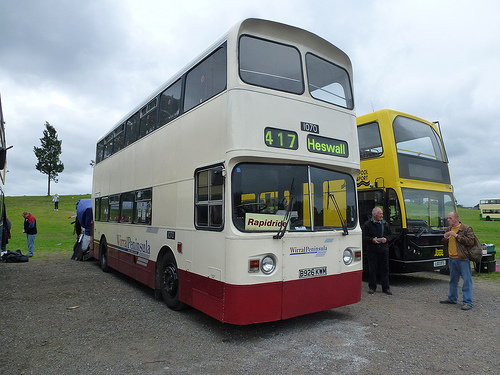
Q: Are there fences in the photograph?
A: No, there are no fences.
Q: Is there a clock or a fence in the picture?
A: No, there are no fences or clocks.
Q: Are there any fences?
A: No, there are no fences.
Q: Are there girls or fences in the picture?
A: No, there are no fences or girls.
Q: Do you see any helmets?
A: No, there are no helmets.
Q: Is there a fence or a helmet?
A: No, there are no helmets or fences.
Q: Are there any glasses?
A: No, there are no glasses.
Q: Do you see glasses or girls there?
A: No, there are no glasses or girls.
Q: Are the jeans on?
A: Yes, the jeans are on.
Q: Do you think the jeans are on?
A: Yes, the jeans are on.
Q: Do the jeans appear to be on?
A: Yes, the jeans are on.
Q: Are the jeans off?
A: No, the jeans are on.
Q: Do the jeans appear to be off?
A: No, the jeans are on.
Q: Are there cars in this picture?
A: No, there are no cars.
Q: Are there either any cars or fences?
A: No, there are no cars or fences.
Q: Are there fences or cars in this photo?
A: No, there are no cars or fences.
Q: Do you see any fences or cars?
A: No, there are no cars or fences.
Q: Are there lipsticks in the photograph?
A: No, there are no lipsticks.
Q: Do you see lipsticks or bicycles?
A: No, there are no lipsticks or bicycles.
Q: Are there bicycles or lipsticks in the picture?
A: No, there are no lipsticks or bicycles.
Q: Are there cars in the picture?
A: No, there are no cars.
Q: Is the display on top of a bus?
A: Yes, the display is on top of a bus.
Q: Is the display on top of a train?
A: No, the display is on top of a bus.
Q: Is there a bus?
A: Yes, there is a bus.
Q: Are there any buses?
A: Yes, there is a bus.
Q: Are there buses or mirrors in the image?
A: Yes, there is a bus.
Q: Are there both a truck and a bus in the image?
A: No, there is a bus but no trucks.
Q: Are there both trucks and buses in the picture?
A: No, there is a bus but no trucks.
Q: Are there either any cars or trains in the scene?
A: No, there are no cars or trains.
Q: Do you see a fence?
A: No, there are no fences.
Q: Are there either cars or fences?
A: No, there are no fences or cars.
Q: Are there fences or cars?
A: No, there are no fences or cars.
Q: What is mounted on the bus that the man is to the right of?
A: The sign is mounted on the bus.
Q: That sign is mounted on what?
A: The sign is mounted on the bus.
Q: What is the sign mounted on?
A: The sign is mounted on the bus.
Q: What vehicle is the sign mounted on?
A: The sign is mounted on the bus.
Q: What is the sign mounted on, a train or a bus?
A: The sign is mounted on a bus.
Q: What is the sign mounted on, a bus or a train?
A: The sign is mounted on a bus.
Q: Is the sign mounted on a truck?
A: No, the sign is mounted on the bus.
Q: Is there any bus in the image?
A: Yes, there is a bus.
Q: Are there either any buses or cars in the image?
A: Yes, there is a bus.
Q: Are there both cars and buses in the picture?
A: No, there is a bus but no cars.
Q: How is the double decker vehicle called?
A: The vehicle is a bus.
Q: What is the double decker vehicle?
A: The vehicle is a bus.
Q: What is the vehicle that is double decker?
A: The vehicle is a bus.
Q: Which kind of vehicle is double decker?
A: The vehicle is a bus.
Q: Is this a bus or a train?
A: This is a bus.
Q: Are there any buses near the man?
A: Yes, there is a bus near the man.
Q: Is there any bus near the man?
A: Yes, there is a bus near the man.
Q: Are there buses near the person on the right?
A: Yes, there is a bus near the man.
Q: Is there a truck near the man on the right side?
A: No, there is a bus near the man.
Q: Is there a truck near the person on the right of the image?
A: No, there is a bus near the man.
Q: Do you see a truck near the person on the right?
A: No, there is a bus near the man.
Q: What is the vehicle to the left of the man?
A: The vehicle is a bus.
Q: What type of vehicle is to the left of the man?
A: The vehicle is a bus.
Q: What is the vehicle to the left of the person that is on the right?
A: The vehicle is a bus.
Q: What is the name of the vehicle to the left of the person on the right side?
A: The vehicle is a bus.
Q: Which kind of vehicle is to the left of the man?
A: The vehicle is a bus.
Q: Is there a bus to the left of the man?
A: Yes, there is a bus to the left of the man.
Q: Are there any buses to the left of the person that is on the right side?
A: Yes, there is a bus to the left of the man.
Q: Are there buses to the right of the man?
A: No, the bus is to the left of the man.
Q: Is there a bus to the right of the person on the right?
A: No, the bus is to the left of the man.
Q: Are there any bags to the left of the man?
A: No, there is a bus to the left of the man.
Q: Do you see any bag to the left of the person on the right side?
A: No, there is a bus to the left of the man.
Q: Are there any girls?
A: No, there are no girls.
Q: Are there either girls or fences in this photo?
A: No, there are no girls or fences.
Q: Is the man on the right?
A: Yes, the man is on the right of the image.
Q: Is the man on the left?
A: No, the man is on the right of the image.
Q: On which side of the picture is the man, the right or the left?
A: The man is on the right of the image.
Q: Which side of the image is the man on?
A: The man is on the right of the image.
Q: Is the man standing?
A: Yes, the man is standing.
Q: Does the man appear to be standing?
A: Yes, the man is standing.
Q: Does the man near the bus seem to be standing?
A: Yes, the man is standing.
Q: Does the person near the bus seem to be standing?
A: Yes, the man is standing.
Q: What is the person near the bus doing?
A: The man is standing.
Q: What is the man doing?
A: The man is standing.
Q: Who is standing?
A: The man is standing.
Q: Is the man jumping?
A: No, the man is standing.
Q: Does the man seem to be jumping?
A: No, the man is standing.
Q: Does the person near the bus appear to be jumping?
A: No, the man is standing.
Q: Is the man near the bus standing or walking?
A: The man is standing.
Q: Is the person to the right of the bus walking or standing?
A: The man is standing.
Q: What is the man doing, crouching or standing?
A: The man is standing.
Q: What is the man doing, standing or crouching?
A: The man is standing.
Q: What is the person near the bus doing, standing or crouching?
A: The man is standing.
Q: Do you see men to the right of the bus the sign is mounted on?
A: Yes, there is a man to the right of the bus.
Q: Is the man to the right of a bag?
A: No, the man is to the right of the bus.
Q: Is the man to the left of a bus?
A: No, the man is to the right of a bus.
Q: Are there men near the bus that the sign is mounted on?
A: Yes, there is a man near the bus.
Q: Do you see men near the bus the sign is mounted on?
A: Yes, there is a man near the bus.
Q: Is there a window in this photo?
A: Yes, there is a window.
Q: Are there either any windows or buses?
A: Yes, there is a window.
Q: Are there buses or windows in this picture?
A: Yes, there is a window.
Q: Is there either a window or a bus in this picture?
A: Yes, there is a window.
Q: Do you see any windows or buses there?
A: Yes, there is a window.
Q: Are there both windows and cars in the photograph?
A: No, there is a window but no cars.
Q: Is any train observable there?
A: No, there are no trains.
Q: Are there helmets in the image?
A: No, there are no helmets.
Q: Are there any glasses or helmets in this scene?
A: No, there are no helmets or glasses.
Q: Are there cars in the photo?
A: No, there are no cars.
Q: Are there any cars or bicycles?
A: No, there are no cars or bicycles.